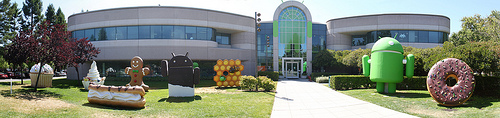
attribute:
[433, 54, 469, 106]
donut — pink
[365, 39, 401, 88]
android — green, large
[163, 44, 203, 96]
statue — large, big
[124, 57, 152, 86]
gingerbread — large, man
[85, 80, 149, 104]
cupcake — large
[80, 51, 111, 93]
ice cream — large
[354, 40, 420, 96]
robot — green, sculpture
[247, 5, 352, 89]
building — multi story, entrance, window, background, round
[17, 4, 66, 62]
tree — tall, forest, green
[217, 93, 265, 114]
grass — green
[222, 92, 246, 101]
field — green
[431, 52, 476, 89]
doughnut — pink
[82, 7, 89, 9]
sky — blue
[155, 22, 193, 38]
window — glass, small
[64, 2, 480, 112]
picture — outdoor, during day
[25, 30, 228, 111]
dessert — large